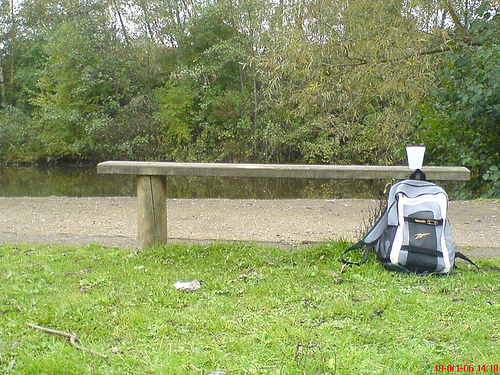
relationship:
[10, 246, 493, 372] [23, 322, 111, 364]
grass has a twig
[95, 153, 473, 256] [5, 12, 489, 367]
bench in park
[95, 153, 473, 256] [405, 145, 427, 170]
bench has a drink on it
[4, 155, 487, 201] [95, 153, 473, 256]
lake behind a bench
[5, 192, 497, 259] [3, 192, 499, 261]
path for walking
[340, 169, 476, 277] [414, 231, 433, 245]
backpack has a logo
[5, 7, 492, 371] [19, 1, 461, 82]
picture of day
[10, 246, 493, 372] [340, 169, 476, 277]
ground has a backpack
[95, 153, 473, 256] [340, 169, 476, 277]
bench has a backpack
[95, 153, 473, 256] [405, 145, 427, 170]
bench has a cup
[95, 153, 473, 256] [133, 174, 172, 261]
bench has a leg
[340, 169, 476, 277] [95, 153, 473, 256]
backpack next to a bench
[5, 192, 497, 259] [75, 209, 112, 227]
path of gravel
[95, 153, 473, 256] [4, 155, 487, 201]
bench next to pond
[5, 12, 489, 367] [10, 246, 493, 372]
park has grass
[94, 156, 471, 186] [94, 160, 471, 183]
board used as board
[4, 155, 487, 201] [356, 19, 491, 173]
water near bushes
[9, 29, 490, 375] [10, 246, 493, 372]
area with grass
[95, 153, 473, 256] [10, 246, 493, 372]
bench by grass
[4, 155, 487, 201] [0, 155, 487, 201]
pond with lake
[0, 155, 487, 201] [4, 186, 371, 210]
lake has an edge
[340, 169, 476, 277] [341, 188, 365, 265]
backpack has black straps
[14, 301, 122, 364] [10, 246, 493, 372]
twig on grass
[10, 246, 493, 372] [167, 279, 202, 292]
grass has litter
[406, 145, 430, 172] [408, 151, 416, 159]
cup of white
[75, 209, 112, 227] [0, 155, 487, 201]
gravel by lake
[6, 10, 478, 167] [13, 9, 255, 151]
group of trees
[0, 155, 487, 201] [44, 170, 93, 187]
lake has a reflection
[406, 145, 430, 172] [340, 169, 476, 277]
cup by backpack